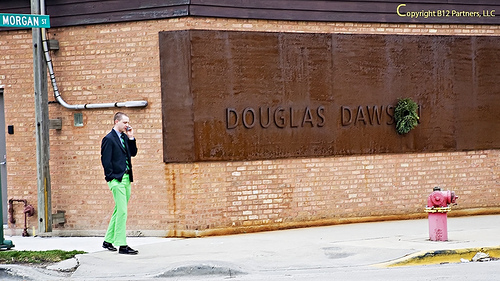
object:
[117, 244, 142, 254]
shoes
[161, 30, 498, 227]
wall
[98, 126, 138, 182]
blue jacket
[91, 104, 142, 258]
man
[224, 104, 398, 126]
name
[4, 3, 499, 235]
building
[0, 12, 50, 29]
sign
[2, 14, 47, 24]
morgan st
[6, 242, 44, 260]
grass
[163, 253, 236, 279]
slope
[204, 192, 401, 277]
sidewalk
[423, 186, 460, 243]
fire hydrant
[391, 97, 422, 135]
wreath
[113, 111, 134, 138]
man cell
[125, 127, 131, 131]
cell phone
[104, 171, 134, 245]
green pants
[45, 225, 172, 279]
sidewalk